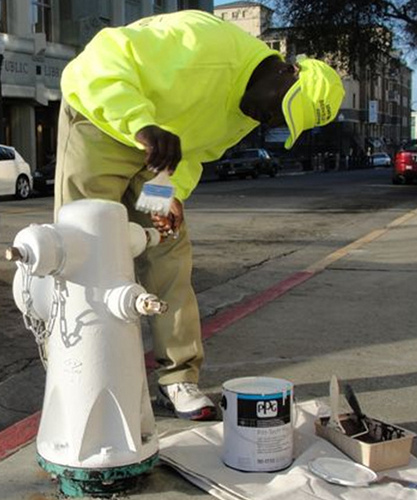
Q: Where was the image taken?
A: It was taken at the street.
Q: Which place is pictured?
A: It is a street.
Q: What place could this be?
A: It is a street.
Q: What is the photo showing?
A: It is showing a street.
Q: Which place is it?
A: It is a street.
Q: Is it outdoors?
A: Yes, it is outdoors.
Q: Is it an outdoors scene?
A: Yes, it is outdoors.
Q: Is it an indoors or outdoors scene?
A: It is outdoors.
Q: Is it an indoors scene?
A: No, it is outdoors.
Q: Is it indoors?
A: No, it is outdoors.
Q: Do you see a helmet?
A: No, there are no helmets.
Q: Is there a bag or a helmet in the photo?
A: No, there are no helmets or bags.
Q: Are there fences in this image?
A: No, there are no fences.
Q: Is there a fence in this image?
A: No, there are no fences.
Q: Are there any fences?
A: No, there are no fences.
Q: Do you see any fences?
A: No, there are no fences.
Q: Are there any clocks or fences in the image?
A: No, there are no fences or clocks.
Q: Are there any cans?
A: Yes, there is a can.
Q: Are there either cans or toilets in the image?
A: Yes, there is a can.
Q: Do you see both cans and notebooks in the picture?
A: No, there is a can but no notebooks.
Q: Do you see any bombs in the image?
A: No, there are no bombs.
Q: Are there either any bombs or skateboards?
A: No, there are no bombs or skateboards.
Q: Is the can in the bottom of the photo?
A: Yes, the can is in the bottom of the image.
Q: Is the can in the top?
A: No, the can is in the bottom of the image.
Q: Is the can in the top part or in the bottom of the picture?
A: The can is in the bottom of the image.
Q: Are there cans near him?
A: Yes, there is a can near the man.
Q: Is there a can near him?
A: Yes, there is a can near the man.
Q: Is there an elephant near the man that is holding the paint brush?
A: No, there is a can near the man.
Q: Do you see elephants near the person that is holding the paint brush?
A: No, there is a can near the man.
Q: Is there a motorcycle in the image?
A: No, there are no motorcycles.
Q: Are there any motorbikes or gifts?
A: No, there are no motorbikes or gifts.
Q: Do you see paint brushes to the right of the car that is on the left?
A: Yes, there is a paint brush to the right of the car.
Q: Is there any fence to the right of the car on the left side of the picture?
A: No, there is a paint brush to the right of the car.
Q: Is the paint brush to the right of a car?
A: Yes, the paint brush is to the right of a car.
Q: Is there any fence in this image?
A: No, there are no fences.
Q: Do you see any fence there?
A: No, there are no fences.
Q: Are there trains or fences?
A: No, there are no fences or trains.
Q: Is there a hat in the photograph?
A: Yes, there is a hat.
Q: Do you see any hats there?
A: Yes, there is a hat.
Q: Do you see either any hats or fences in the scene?
A: Yes, there is a hat.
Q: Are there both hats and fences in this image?
A: No, there is a hat but no fences.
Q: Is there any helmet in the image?
A: No, there are no helmets.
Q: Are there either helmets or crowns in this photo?
A: No, there are no helmets or crowns.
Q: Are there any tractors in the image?
A: No, there are no tractors.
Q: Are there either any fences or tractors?
A: No, there are no tractors or fences.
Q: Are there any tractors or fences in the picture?
A: No, there are no tractors or fences.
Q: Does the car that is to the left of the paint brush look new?
A: No, the car is old.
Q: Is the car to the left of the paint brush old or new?
A: The car is old.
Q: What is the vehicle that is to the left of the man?
A: The vehicle is a car.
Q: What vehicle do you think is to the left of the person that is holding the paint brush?
A: The vehicle is a car.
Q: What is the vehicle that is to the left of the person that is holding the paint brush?
A: The vehicle is a car.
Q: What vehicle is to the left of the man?
A: The vehicle is a car.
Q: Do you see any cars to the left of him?
A: Yes, there is a car to the left of the man.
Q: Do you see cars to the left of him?
A: Yes, there is a car to the left of the man.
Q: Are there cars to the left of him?
A: Yes, there is a car to the left of the man.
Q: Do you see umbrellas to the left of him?
A: No, there is a car to the left of the man.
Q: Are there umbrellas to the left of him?
A: No, there is a car to the left of the man.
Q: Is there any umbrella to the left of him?
A: No, there is a car to the left of the man.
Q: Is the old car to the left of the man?
A: Yes, the car is to the left of the man.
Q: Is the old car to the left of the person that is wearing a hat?
A: Yes, the car is to the left of the man.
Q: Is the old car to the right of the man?
A: No, the car is to the left of the man.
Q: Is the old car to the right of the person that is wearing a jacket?
A: No, the car is to the left of the man.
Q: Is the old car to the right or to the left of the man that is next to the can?
A: The car is to the left of the man.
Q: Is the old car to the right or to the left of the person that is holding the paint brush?
A: The car is to the left of the man.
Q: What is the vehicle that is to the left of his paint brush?
A: The vehicle is a car.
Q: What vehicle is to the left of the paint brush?
A: The vehicle is a car.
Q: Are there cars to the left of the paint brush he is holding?
A: Yes, there is a car to the left of the paint brush.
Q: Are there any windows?
A: Yes, there is a window.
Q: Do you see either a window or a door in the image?
A: Yes, there is a window.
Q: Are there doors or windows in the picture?
A: Yes, there is a window.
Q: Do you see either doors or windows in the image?
A: Yes, there is a window.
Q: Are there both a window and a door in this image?
A: No, there is a window but no doors.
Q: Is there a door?
A: No, there are no doors.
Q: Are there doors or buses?
A: No, there are no doors or buses.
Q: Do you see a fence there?
A: No, there are no fences.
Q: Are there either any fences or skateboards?
A: No, there are no fences or skateboards.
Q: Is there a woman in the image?
A: No, there are no women.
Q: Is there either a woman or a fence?
A: No, there are no women or fences.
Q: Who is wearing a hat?
A: The man is wearing a hat.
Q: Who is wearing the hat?
A: The man is wearing a hat.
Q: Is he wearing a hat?
A: Yes, the man is wearing a hat.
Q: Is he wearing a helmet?
A: No, the man is wearing a hat.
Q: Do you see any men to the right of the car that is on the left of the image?
A: Yes, there is a man to the right of the car.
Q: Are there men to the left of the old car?
A: No, the man is to the right of the car.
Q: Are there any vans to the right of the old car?
A: No, there is a man to the right of the car.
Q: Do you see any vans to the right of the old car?
A: No, there is a man to the right of the car.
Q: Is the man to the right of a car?
A: Yes, the man is to the right of a car.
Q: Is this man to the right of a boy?
A: No, the man is to the right of a car.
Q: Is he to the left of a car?
A: No, the man is to the right of a car.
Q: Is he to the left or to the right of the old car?
A: The man is to the right of the car.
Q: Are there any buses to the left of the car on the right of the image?
A: No, there is a man to the left of the car.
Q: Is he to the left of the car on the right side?
A: Yes, the man is to the left of the car.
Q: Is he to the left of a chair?
A: No, the man is to the left of the car.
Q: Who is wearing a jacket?
A: The man is wearing a jacket.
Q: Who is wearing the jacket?
A: The man is wearing a jacket.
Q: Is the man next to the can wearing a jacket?
A: Yes, the man is wearing a jacket.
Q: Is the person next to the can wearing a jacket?
A: Yes, the man is wearing a jacket.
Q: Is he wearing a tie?
A: No, the man is wearing a jacket.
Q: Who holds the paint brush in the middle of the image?
A: The man holds the paint brush.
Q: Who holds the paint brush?
A: The man holds the paint brush.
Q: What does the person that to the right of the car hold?
A: The man holds the paint brush.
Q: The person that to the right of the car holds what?
A: The man holds the paint brush.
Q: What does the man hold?
A: The man holds the paint brush.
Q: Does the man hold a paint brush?
A: Yes, the man holds a paint brush.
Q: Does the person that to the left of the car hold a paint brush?
A: Yes, the man holds a paint brush.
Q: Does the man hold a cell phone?
A: No, the man holds a paint brush.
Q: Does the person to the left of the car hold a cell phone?
A: No, the man holds a paint brush.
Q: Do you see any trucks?
A: No, there are no trucks.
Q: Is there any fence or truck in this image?
A: No, there are no trucks or fences.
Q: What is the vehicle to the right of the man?
A: The vehicle is a car.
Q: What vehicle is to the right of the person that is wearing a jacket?
A: The vehicle is a car.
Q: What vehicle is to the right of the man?
A: The vehicle is a car.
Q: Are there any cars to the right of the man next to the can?
A: Yes, there is a car to the right of the man.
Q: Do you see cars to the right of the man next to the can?
A: Yes, there is a car to the right of the man.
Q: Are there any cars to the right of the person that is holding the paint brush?
A: Yes, there is a car to the right of the man.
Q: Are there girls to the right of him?
A: No, there is a car to the right of the man.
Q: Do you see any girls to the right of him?
A: No, there is a car to the right of the man.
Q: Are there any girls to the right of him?
A: No, there is a car to the right of the man.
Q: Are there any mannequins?
A: No, there are no mannequins.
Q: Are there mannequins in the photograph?
A: No, there are no mannequins.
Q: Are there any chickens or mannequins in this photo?
A: No, there are no mannequins or chickens.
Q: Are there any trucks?
A: No, there are no trucks.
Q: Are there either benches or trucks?
A: No, there are no trucks or benches.